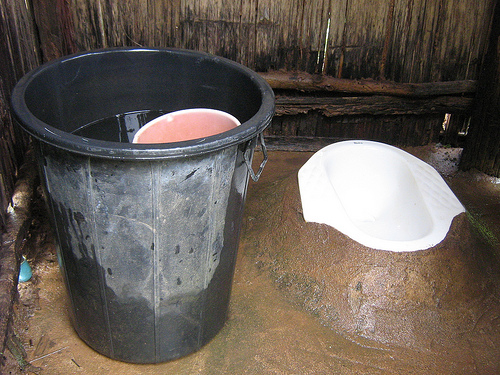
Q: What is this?
A: Bucket.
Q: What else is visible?
A: Toilet.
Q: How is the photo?
A: Clear.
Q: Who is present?
A: No one.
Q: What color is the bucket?
A: Black.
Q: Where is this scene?
A: In a corner area.